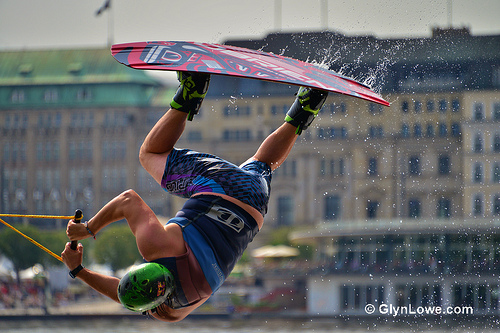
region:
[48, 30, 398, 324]
a man upside down on a water board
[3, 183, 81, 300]
a man holding on to a handle and rope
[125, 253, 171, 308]
a man wearing a green helmet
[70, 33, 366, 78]
a red and blue water board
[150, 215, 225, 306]
a man wearing a life vest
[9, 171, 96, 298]
a yellow rope with a hangle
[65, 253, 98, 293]
a man wearing a black watch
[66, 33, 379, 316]
a man doing a trick on a water board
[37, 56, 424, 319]
a man doing a flip on a water board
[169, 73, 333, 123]
boots attached to a water board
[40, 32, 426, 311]
person wake boarding in lake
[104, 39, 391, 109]
red and black wake board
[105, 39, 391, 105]
bottom of red wake board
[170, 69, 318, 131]
green and black wake board shoes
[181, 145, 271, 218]
black and purple swim trunks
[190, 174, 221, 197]
blue stripe on swim trunks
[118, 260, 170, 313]
green helmet on head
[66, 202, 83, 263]
black tow rope handle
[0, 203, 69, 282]
yellow tow rope connected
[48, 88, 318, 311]
man holding onto tow rope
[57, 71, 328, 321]
A person on a kite surfing board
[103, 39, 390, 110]
a kite surfing board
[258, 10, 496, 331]
a splash of water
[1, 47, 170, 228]
A large stone building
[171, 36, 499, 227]
A large stone building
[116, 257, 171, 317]
a green helmet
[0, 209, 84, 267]
some yellow rope on a handle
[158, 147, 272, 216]
A pair of blue, black, and purple shorts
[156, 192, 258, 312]
a sleeveless shirt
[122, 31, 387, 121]
wakeboard on a persons feet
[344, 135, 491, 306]
buildings in the distance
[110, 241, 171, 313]
green helmet ona person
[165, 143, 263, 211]
colorful shorts on a person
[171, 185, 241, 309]
tank top on a person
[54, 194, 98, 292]
hands holding on a handle bar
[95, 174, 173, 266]
muscles on a bicep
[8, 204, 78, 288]
yellow rop attatched to a handle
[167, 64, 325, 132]
feet attatched to a wake board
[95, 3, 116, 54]
flag flying on top of a building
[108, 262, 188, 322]
green safety helmet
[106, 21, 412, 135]
pink wakeboard with green boots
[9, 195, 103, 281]
hands holding onto a safety handle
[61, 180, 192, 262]
man's upside down arm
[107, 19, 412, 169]
lower half of man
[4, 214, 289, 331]
upper half of man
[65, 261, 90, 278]
black wrist watch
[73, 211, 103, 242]
small bracelet on man's right arm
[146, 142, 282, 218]
blue and black checkered swim shorts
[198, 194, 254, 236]
athletic company logo on blue shirt